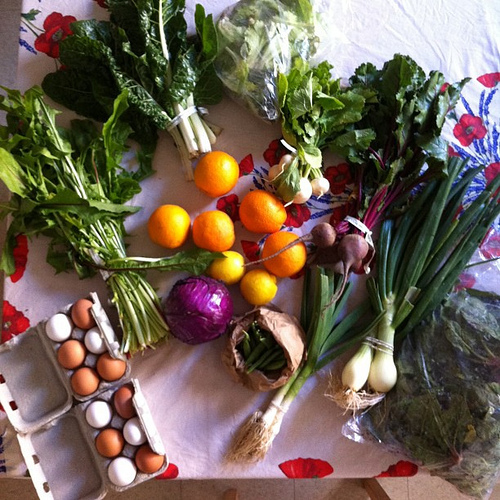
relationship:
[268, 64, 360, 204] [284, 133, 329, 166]
raddishes in bundle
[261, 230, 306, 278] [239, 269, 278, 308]
orange and lemon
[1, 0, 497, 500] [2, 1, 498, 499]
vegetables on table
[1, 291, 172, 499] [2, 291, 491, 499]
eggs in carton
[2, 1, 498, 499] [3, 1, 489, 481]
table has tablecloth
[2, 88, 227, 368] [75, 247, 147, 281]
spinach in bunch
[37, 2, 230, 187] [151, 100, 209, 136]
kale i bunch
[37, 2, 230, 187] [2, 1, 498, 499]
kale on table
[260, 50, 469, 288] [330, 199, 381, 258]
beetroot in bunch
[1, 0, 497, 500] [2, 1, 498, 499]
food on table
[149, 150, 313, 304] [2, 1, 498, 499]
fruits of table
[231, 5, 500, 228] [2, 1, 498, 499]
light on table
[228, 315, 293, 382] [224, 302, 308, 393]
edamame in bag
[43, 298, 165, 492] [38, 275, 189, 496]
half dozen of eggs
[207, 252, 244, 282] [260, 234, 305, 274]
lemon between orange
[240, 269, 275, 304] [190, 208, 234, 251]
lemon between orange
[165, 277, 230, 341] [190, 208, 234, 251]
onion between orange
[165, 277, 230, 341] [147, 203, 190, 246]
onion between orange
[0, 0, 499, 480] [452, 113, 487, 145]
table cloth with flower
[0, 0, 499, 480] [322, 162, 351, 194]
table cloth with flower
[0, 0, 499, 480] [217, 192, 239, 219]
table cloth with flower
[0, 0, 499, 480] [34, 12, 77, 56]
table cloth with flower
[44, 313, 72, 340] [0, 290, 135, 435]
egg in carton